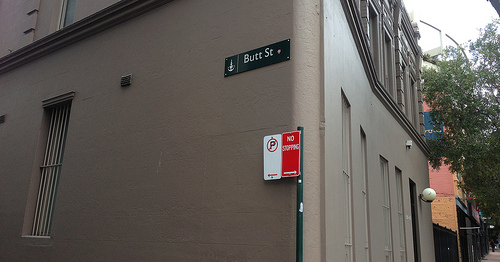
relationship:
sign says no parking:
[256, 125, 301, 184] [281, 127, 301, 149]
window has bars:
[22, 86, 79, 243] [34, 106, 63, 226]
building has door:
[4, 1, 443, 260] [406, 175, 428, 260]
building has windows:
[4, 1, 443, 260] [354, 2, 428, 131]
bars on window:
[26, 98, 69, 238] [19, 84, 82, 240]